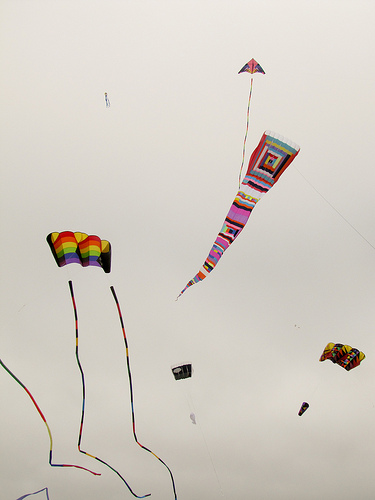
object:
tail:
[175, 189, 258, 303]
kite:
[174, 132, 301, 302]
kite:
[45, 229, 113, 274]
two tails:
[67, 278, 180, 500]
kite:
[170, 363, 195, 381]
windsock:
[297, 400, 309, 418]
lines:
[203, 260, 213, 270]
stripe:
[225, 217, 245, 229]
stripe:
[231, 201, 253, 213]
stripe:
[204, 260, 214, 271]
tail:
[109, 287, 181, 499]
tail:
[67, 279, 154, 499]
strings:
[238, 70, 255, 193]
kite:
[317, 341, 369, 374]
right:
[310, 296, 373, 391]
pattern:
[173, 198, 251, 303]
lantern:
[237, 57, 266, 190]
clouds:
[0, 1, 374, 498]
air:
[0, 4, 374, 498]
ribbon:
[0, 353, 103, 478]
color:
[220, 194, 252, 234]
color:
[215, 236, 229, 248]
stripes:
[50, 247, 104, 261]